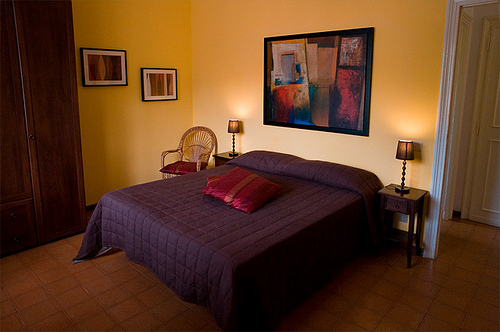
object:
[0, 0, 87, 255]
cabinet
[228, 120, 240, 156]
lamp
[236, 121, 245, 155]
shade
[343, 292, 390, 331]
tile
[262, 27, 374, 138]
frame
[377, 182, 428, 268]
right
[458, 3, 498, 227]
door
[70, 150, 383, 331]
bed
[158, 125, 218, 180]
chair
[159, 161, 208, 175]
red cushion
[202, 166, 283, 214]
pillow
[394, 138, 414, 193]
lamp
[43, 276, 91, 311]
tile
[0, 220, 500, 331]
floor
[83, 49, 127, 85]
painting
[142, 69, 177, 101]
painting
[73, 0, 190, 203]
wall